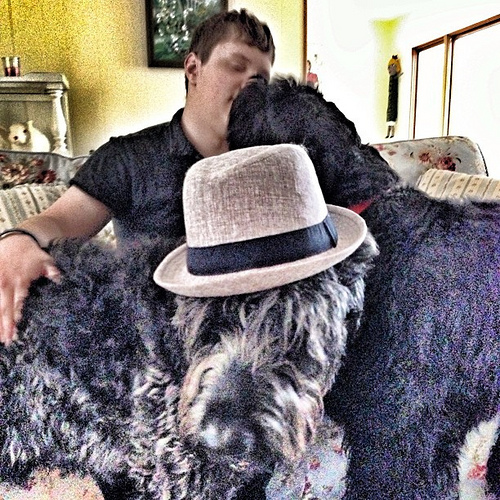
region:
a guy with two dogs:
[41, 5, 449, 492]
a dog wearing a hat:
[140, 143, 368, 347]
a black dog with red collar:
[260, 85, 450, 230]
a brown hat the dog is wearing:
[137, 134, 373, 303]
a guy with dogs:
[160, 10, 262, 130]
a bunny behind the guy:
[0, 115, 46, 157]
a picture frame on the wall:
[126, 0, 173, 75]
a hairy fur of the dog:
[256, 355, 312, 450]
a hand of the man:
[0, 235, 65, 343]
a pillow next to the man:
[416, 163, 481, 193]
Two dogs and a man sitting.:
[133, 78, 466, 428]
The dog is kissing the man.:
[168, 45, 400, 221]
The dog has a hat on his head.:
[156, 145, 365, 292]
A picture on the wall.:
[123, 2, 230, 64]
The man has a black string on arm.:
[7, 221, 58, 255]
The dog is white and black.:
[66, 275, 351, 445]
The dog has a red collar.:
[348, 186, 417, 222]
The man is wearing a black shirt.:
[87, 131, 169, 219]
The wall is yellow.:
[63, 30, 130, 123]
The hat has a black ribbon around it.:
[161, 227, 340, 280]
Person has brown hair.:
[206, 10, 256, 44]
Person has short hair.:
[164, 21, 301, 49]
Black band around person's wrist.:
[3, 218, 69, 275]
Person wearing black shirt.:
[129, 151, 169, 176]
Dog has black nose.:
[191, 428, 261, 459]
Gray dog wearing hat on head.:
[171, 219, 372, 318]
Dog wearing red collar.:
[346, 181, 414, 243]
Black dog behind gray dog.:
[334, 142, 479, 376]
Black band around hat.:
[196, 236, 324, 263]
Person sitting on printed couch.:
[58, 151, 170, 277]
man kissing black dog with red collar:
[184, 6, 328, 143]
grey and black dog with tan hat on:
[149, 144, 354, 469]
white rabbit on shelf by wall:
[5, 116, 51, 157]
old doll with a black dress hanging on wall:
[381, 56, 400, 140]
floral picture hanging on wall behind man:
[143, 0, 228, 70]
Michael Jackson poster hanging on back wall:
[305, 53, 323, 95]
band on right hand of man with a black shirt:
[0, 226, 40, 243]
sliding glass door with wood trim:
[407, 37, 449, 135]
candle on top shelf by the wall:
[0, 55, 20, 73]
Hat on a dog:
[126, 133, 399, 358]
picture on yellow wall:
[116, 0, 312, 94]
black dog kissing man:
[217, 73, 349, 178]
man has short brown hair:
[178, 6, 293, 111]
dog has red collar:
[348, 171, 426, 266]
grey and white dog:
[43, 297, 348, 479]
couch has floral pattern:
[386, 110, 474, 246]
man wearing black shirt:
[76, 111, 314, 346]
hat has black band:
[163, 213, 422, 293]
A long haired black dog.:
[227, 81, 499, 498]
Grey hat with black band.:
[151, 143, 367, 300]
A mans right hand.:
[1, 231, 65, 345]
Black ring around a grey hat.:
[185, 213, 339, 277]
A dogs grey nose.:
[194, 427, 246, 455]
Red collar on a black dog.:
[348, 196, 380, 212]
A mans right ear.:
[181, 53, 201, 85]